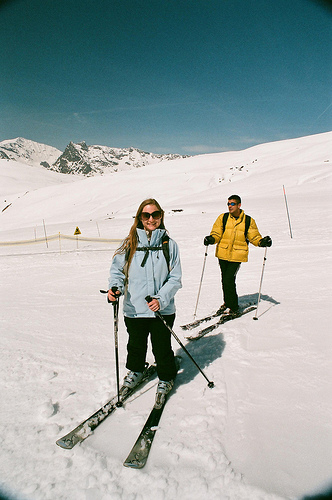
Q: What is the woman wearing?
A: Sunglasses.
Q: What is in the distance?
A: Mountains.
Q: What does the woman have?
A: Long hair.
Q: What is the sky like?
A: Clear and blue.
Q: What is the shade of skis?
A: Black.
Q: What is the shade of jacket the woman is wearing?
A: Blue.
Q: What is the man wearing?
A: Blue sunglasses.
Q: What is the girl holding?
A: Ski poles.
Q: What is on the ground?
A: Snow.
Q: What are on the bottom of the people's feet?
A: Skis.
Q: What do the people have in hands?
A: Ski poles.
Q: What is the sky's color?
A: Blue.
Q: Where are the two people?
A: On skis.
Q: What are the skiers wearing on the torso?
A: Jackets.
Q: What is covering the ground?
A: Snow.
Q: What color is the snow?
A: White.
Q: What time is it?
A: Daytime.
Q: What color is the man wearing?
A: Yellow.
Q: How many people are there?
A: Two.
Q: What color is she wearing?
A: Blue.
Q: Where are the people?
A: In the snow.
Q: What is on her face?
A: Glasses.